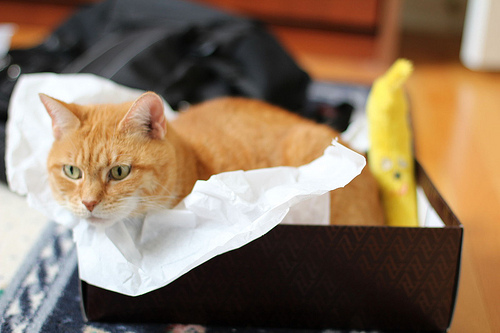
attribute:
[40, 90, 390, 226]
cat — beautiful, orange, yellow, striped, tabby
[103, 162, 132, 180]
eye —  green,  cat's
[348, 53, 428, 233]
banana — yellow 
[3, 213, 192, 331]
rug — white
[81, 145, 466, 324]
box — black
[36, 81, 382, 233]
cat — orange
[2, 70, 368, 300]
paper — white, tissue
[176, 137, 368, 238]
napkin — white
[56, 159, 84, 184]
eye — light yellowish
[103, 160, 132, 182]
eye — light yellowish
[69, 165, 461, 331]
shoe box — dark brown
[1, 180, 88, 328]
carpet — white, dark grey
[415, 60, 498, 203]
flooring — light, hardwood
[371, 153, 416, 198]
face — smiling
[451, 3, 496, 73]
door — white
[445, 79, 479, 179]
floor — shiny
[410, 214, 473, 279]
shoe box — cracked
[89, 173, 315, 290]
paper — crinkled, white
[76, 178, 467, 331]
box — large, black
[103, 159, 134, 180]
eye — beautiful, green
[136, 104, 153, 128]
whiskers — white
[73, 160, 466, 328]
box — brown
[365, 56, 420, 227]
banana — yellow, large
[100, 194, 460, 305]
box — black